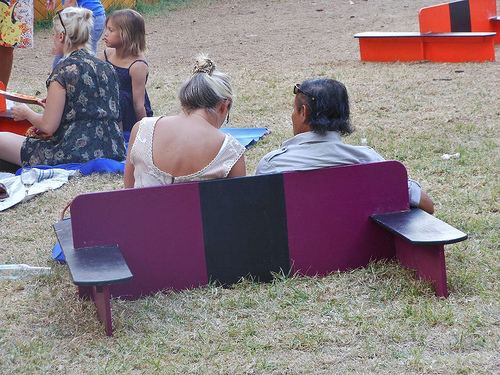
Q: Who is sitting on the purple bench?
A: Man and woman.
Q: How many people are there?
A: 6.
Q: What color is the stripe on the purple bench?
A: Black.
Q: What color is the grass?
A: Brown.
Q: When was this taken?
A: Daytime.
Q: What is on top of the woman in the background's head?
A: Sunglasses.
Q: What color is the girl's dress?
A: Blue.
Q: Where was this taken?
A: An an outdoor concert.